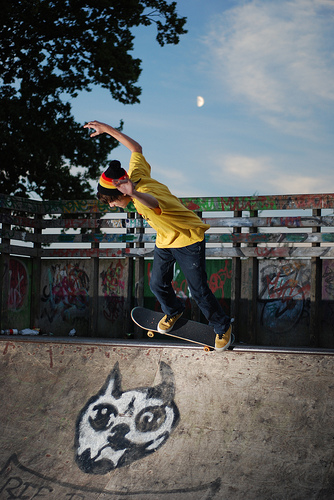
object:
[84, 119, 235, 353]
boy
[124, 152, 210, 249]
shirt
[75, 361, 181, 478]
dog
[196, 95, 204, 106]
half moon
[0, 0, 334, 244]
sky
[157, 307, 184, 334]
tennis shoe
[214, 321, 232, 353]
tennis shoe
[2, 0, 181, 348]
tree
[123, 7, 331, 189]
cloud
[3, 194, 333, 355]
fence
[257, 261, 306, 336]
number 5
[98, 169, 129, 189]
hat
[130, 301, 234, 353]
skateboard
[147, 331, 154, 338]
wheel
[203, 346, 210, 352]
wheel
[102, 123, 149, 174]
arm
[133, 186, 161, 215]
arm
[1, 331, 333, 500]
ramp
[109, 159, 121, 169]
pom pom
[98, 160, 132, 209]
head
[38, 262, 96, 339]
graffiti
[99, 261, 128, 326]
graffiti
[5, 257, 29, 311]
graffiti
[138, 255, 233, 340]
graffiti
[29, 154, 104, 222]
branch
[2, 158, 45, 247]
brance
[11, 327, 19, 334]
trash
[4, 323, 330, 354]
platform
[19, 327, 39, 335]
trash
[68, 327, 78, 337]
trash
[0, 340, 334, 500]
mark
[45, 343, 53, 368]
mark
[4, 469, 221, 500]
writing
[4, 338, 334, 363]
band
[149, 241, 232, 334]
jeans